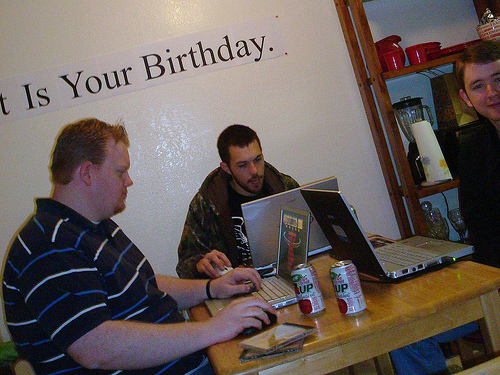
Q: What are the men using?
A: Laptops.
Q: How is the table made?
A: Of wood.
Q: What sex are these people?
A: Male.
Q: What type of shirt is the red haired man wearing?
A: Striped.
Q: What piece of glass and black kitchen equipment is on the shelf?
A: A blender.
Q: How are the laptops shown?
A: Open.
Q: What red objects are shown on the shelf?
A: Cups and plates.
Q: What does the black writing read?
A: Is Your Birthday.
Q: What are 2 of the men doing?
A: Working on laptops.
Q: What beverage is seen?
A: 7up.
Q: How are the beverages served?
A: Cans.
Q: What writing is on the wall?
A: Is your birthday.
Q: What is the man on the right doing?
A: Smiling at camera.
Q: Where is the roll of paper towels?
A: Shelf in front of blender.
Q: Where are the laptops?
A: Wood table.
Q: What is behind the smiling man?
A: Wood shelf.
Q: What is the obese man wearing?
A: Striped polo shirt.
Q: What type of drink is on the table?
A: 7up.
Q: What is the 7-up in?
A: A can.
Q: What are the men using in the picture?
A: Laptops.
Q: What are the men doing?
A: On laptop.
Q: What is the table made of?
A: Wood.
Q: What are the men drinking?
A: Soda.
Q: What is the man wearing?
A: Striped shirt.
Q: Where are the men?
A: Store.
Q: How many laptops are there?
A: Three.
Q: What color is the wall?
A: White.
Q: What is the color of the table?
A: Brown.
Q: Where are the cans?
A: On the table.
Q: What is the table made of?
A: Wood.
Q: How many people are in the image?
A: Three.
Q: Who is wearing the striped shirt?
A: The man on the left.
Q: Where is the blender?
A: On the shelf.